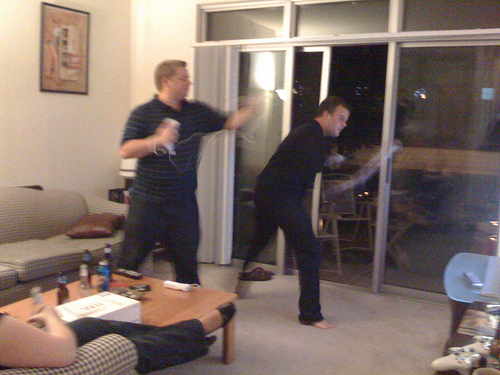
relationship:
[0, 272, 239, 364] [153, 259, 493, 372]
coffee table on ground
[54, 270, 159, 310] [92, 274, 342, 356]
bottles on table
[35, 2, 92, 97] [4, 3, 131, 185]
frame on wall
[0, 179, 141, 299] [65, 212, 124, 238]
sofa with pillow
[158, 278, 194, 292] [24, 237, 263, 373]
game controller on table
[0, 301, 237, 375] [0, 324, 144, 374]
person sitting on sofa chair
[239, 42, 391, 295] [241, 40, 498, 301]
door out to patio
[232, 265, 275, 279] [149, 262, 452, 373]
shoes on floor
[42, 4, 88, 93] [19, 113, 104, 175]
picture on wall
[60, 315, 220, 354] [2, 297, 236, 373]
leg on woman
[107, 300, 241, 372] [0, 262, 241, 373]
leg on coffee table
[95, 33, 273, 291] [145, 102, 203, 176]
man on wii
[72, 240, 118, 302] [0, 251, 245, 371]
drinks on table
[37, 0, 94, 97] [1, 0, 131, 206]
picture on wall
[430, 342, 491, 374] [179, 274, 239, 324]
contoller on table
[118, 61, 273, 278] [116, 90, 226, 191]
man in shirt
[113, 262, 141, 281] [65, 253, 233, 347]
remote on table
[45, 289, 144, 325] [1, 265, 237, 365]
box on table